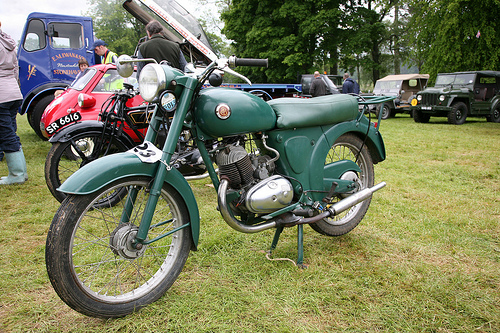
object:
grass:
[0, 113, 497, 330]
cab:
[410, 54, 498, 125]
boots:
[0, 143, 26, 184]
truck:
[6, 0, 303, 140]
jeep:
[408, 70, 499, 125]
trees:
[78, 1, 498, 86]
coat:
[0, 27, 22, 104]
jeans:
[0, 97, 31, 185]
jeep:
[365, 69, 427, 117]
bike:
[42, 55, 399, 319]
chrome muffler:
[215, 177, 387, 233]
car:
[40, 63, 203, 212]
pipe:
[296, 181, 387, 226]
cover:
[366, 71, 432, 122]